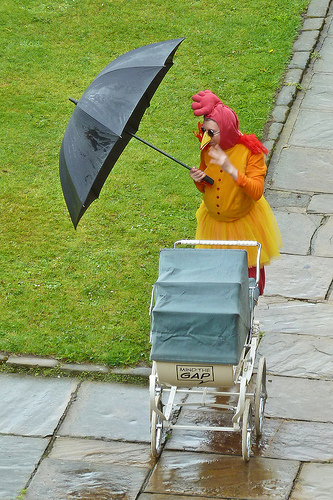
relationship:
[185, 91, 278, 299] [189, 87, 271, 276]
woman wearing a costume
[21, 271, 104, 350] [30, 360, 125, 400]
grass lined with bricks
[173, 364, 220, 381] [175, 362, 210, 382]
sign has letters